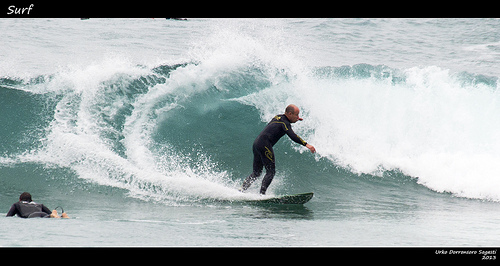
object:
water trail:
[28, 55, 248, 204]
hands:
[306, 143, 316, 153]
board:
[14, 206, 69, 218]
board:
[218, 192, 314, 204]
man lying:
[4, 192, 69, 218]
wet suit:
[5, 201, 51, 218]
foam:
[8, 29, 498, 91]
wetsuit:
[235, 115, 308, 194]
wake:
[75, 117, 170, 193]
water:
[332, 171, 434, 236]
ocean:
[2, 17, 498, 259]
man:
[238, 104, 316, 195]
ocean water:
[2, 17, 499, 244]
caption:
[434, 248, 497, 260]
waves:
[0, 57, 498, 177]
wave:
[7, 45, 499, 207]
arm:
[284, 123, 310, 148]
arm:
[298, 118, 304, 121]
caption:
[7, 3, 35, 15]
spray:
[72, 34, 197, 113]